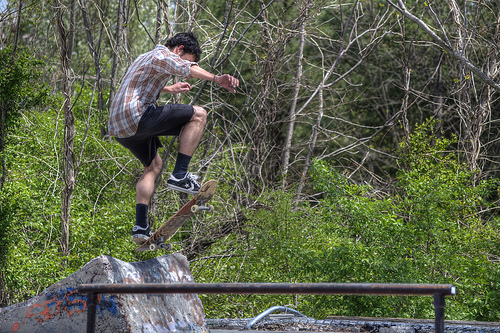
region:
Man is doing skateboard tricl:
[106, 30, 236, 258]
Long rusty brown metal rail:
[74, 280, 462, 332]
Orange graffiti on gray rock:
[9, 275, 96, 329]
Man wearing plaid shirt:
[110, 28, 242, 246]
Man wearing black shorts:
[107, 30, 241, 247]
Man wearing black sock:
[109, 28, 238, 243]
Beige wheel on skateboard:
[190, 202, 198, 218]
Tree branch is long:
[292, 20, 386, 116]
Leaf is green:
[397, 215, 404, 226]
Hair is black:
[159, 30, 204, 63]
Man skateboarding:
[45, 2, 281, 247]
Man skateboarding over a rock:
[23, 20, 315, 305]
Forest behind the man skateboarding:
[35, 47, 480, 287]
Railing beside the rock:
[50, 262, 466, 327]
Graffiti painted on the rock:
[17, 282, 108, 322]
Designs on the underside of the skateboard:
[122, 191, 192, 229]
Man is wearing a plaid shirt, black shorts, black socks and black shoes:
[110, 50, 220, 248]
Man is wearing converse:
[155, 157, 230, 192]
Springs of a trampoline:
[235, 305, 475, 330]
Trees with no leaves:
[267, 24, 479, 153]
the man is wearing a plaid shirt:
[111, 43, 195, 137]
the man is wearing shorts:
[111, 98, 194, 158]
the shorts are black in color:
[111, 101, 196, 161]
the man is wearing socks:
[126, 152, 193, 224]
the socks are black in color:
[128, 152, 193, 229]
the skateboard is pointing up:
[132, 175, 217, 255]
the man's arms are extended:
[142, 42, 242, 97]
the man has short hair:
[165, 30, 201, 60]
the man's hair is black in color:
[163, 28, 200, 58]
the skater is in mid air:
[97, 27, 247, 257]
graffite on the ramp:
[31, 272, 119, 330]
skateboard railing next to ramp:
[51, 249, 460, 307]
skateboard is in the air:
[106, 108, 241, 265]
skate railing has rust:
[97, 273, 468, 302]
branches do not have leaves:
[250, 20, 492, 156]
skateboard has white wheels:
[144, 194, 215, 263]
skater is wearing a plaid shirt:
[110, 43, 177, 150]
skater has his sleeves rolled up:
[110, 43, 212, 83]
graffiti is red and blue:
[11, 266, 162, 331]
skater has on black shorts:
[105, 92, 212, 150]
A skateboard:
[98, 177, 303, 252]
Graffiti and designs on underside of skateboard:
[117, 167, 208, 262]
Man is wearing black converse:
[90, 172, 195, 197]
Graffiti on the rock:
[5, 245, 146, 326]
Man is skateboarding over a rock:
[25, 60, 210, 325]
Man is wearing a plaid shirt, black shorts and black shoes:
[105, 30, 235, 235]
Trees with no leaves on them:
[227, 0, 488, 146]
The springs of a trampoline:
[320, 302, 451, 328]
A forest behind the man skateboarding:
[52, 41, 417, 248]